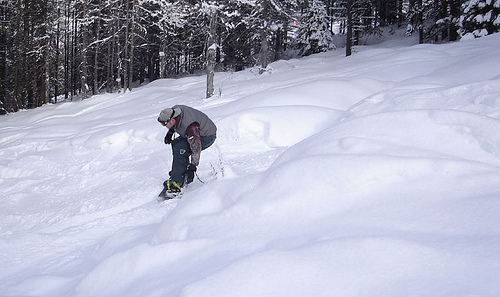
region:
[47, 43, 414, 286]
a man snowboarding outside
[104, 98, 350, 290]
a man snowbaording on snow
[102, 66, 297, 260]
a man snowboarding on white s now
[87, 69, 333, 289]
a man standing on snowboard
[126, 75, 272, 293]
a man standing on snow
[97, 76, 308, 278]
a man standing on white snow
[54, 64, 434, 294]
white snow covering the ground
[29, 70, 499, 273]
snow covering the ground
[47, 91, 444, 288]
ground covered in snow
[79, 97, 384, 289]
ground covered in white snow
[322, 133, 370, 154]
Small block of snow.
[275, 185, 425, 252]
Hills of snow on the ground.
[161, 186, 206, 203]
Man with two skiis.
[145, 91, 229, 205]
Person going down a slope.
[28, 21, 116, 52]
Snow on top of trres.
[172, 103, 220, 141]
Vest on man's back.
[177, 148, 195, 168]
White patch on jeans.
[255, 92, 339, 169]
Big hole in the snow.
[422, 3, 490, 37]
Tree on the ground with snow.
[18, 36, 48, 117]
Small tree without snow.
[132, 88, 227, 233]
man snow boarding down hill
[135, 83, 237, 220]
man riding snowboard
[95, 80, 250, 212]
man on top of snow board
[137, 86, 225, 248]
man snowboarding on snow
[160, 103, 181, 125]
tan hat on man's head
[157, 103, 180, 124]
tan hat backwards on head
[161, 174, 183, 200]
black and green snow shoes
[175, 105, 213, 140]
tan jacket on man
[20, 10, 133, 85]
tress covered in snow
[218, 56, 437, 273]
large mounds of snow on hill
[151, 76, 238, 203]
a man in the snow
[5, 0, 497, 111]
snow covered trees in the distance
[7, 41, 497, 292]
snow on the ground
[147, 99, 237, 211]
man on a snowboard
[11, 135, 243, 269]
tracks in the white snow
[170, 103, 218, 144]
a man wearing a gray vest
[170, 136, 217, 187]
a man wearing blue ski pants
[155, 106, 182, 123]
a man wearing a tan baseball cap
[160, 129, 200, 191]
a man wearing black gloves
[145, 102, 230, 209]
a man crouching in the snow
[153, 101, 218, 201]
a man on snow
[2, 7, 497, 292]
large pile of snow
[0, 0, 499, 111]
a large woods area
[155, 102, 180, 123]
a man with gray cap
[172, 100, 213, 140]
a man with gray jacket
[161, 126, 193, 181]
a man with black gloves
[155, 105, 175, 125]
safety goggles on man's head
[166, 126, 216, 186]
man with gray pants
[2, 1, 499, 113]
show on tree branches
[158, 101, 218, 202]
a man bending toward the ground